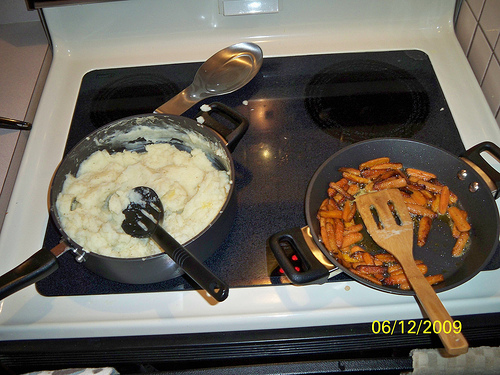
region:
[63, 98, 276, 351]
yummy food on stove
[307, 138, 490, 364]
yummy food on stove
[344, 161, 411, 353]
A spatula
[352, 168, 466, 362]
A spatula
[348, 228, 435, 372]
A spatula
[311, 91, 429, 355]
A spatula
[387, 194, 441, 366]
A spatula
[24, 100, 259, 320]
white food in a pot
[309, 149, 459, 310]
brown food in a pan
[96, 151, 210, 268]
spoon in a bowl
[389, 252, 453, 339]
handle of the spoon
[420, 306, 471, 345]
year in the bottom right corner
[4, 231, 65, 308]
handle of the pan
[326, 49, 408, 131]
stove next to the pan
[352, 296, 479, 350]
writing in yellow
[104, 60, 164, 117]
stove next to potato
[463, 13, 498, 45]
tile on the wall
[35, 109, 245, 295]
pan of mashed potatoes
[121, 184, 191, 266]
black plastic spoon in potato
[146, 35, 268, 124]
silver spoon on stove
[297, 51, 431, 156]
burner on electric stove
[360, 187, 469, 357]
wood spatula in pan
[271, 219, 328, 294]
black handle on pan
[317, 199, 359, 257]
fried carrots in pan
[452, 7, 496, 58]
tile on kitchen wall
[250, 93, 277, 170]
light reflection on stovetop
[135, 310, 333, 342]
white edge on stove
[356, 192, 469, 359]
this is a cooking spoon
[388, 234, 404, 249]
the spoon is wooden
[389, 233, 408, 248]
the spoon is brown in color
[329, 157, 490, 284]
this is a pan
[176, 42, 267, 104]
this is a spoon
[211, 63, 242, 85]
the spoon is metallic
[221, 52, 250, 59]
the spoon is shiny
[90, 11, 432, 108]
this is a gas cooker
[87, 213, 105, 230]
the substance is white in color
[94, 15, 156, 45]
the cooker is white in color